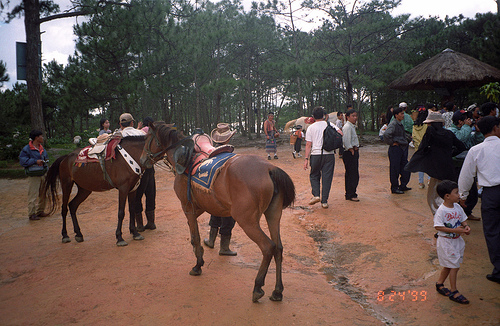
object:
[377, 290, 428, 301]
date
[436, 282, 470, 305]
sandals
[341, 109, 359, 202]
people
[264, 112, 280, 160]
people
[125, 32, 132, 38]
needle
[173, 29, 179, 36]
needle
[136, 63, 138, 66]
needle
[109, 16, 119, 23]
needle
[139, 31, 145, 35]
needle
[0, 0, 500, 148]
pine tree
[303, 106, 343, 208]
man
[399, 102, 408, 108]
cap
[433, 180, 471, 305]
boy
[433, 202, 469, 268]
clothes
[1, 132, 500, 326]
dirt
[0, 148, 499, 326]
clay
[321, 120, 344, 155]
backpack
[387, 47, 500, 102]
hut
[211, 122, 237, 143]
hat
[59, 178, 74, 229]
leg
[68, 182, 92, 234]
leg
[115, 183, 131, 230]
leg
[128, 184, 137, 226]
leg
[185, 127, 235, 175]
saddle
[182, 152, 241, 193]
blanket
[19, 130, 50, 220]
man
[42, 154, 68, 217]
tail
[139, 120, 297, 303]
brown horse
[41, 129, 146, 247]
brown horse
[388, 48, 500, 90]
roof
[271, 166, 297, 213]
tail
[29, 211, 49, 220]
boots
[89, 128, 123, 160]
saddle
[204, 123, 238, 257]
guy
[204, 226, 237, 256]
boots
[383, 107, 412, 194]
man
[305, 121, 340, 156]
shirt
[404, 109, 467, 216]
person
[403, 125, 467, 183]
cape